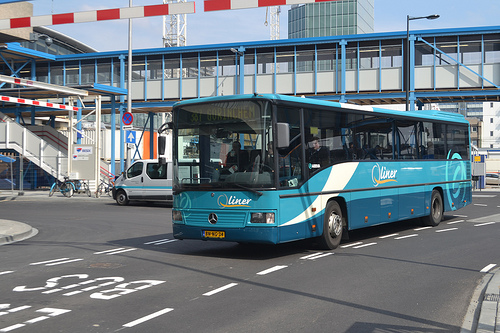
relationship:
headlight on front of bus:
[263, 212, 275, 225] [169, 87, 463, 254]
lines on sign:
[123, 114, 131, 124] [120, 109, 132, 126]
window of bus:
[169, 98, 280, 188] [169, 87, 463, 254]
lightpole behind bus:
[406, 12, 441, 108] [169, 87, 463, 254]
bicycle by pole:
[48, 180, 75, 195] [104, 80, 156, 289]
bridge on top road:
[14, 39, 495, 116] [0, 186, 499, 332]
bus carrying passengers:
[169, 87, 463, 254] [298, 112, 434, 158]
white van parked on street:
[109, 158, 173, 205] [0, 199, 177, 243]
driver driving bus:
[252, 137, 289, 187] [149, 51, 499, 288]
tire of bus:
[321, 197, 345, 250] [169, 87, 463, 254]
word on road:
[10, 271, 165, 307] [0, 188, 498, 331]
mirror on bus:
[276, 122, 291, 148] [159, 93, 481, 239]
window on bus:
[171, 105, 276, 182] [159, 93, 481, 239]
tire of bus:
[321, 206, 345, 246] [158, 87, 478, 258]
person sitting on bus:
[223, 139, 244, 173] [169, 87, 463, 254]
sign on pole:
[115, 105, 142, 128] [100, 25, 152, 90]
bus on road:
[169, 87, 463, 254] [0, 188, 498, 331]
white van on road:
[109, 158, 224, 206] [92, 209, 142, 233]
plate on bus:
[204, 230, 227, 239] [169, 87, 463, 254]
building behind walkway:
[283, 0, 384, 40] [51, 26, 484, 106]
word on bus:
[369, 162, 399, 184] [169, 87, 463, 254]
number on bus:
[179, 105, 263, 126] [169, 87, 463, 254]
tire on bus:
[321, 197, 345, 250] [169, 87, 463, 254]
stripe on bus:
[287, 157, 364, 222] [169, 87, 463, 254]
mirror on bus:
[272, 120, 289, 150] [169, 87, 463, 254]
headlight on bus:
[263, 212, 275, 225] [169, 87, 463, 254]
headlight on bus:
[246, 210, 277, 226] [167, 92, 439, 236]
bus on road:
[156, 92, 474, 250] [26, 239, 478, 322]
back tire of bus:
[421, 187, 446, 229] [169, 87, 463, 254]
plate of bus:
[200, 226, 227, 240] [169, 87, 463, 254]